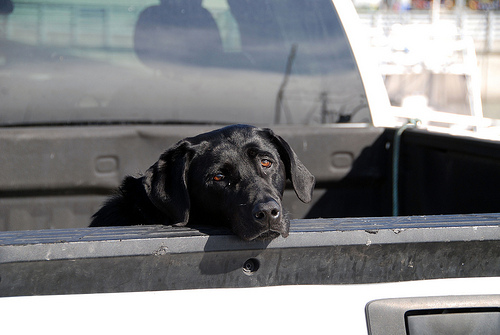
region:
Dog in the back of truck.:
[114, 117, 308, 257]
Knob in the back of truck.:
[326, 149, 359, 171]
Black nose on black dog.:
[253, 204, 290, 228]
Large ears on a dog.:
[131, 148, 199, 223]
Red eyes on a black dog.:
[255, 155, 278, 174]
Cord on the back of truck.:
[386, 105, 406, 230]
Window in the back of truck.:
[11, 3, 351, 113]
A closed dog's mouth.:
[251, 224, 289, 246]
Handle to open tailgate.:
[351, 276, 498, 333]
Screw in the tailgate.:
[241, 255, 262, 273]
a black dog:
[89, 125, 316, 242]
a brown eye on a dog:
[260, 158, 272, 169]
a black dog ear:
[141, 140, 203, 229]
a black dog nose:
[253, 200, 280, 226]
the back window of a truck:
[0, 0, 372, 124]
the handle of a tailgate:
[366, 296, 497, 334]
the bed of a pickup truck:
[0, 126, 498, 232]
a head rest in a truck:
[129, 5, 225, 66]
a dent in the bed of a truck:
[127, 127, 154, 144]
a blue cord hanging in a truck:
[392, 121, 416, 216]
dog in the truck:
[141, 117, 321, 234]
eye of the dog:
[250, 155, 277, 171]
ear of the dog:
[125, 146, 195, 225]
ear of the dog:
[252, 138, 314, 201]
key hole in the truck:
[237, 256, 265, 280]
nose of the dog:
[256, 203, 281, 225]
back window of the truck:
[0, 8, 343, 90]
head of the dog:
[147, 123, 304, 255]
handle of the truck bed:
[372, 295, 489, 333]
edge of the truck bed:
[323, 209, 350, 284]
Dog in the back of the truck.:
[88, 118, 313, 243]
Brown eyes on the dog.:
[203, 148, 280, 188]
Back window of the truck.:
[2, 2, 373, 132]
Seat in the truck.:
[102, 3, 256, 121]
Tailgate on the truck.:
[0, 217, 498, 334]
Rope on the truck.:
[386, 120, 415, 214]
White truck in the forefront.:
[4, 4, 496, 331]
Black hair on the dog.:
[85, 115, 315, 244]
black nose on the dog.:
[244, 195, 284, 227]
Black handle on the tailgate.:
[360, 293, 499, 333]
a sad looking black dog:
[86, 122, 319, 239]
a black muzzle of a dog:
[225, 185, 293, 239]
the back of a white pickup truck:
[0, 219, 497, 334]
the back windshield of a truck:
[0, 2, 375, 120]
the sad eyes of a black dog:
[208, 155, 277, 185]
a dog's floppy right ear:
[147, 141, 197, 230]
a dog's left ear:
[264, 125, 319, 206]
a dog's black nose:
[253, 202, 278, 224]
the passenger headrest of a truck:
[133, 0, 218, 75]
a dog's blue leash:
[390, 120, 425, 214]